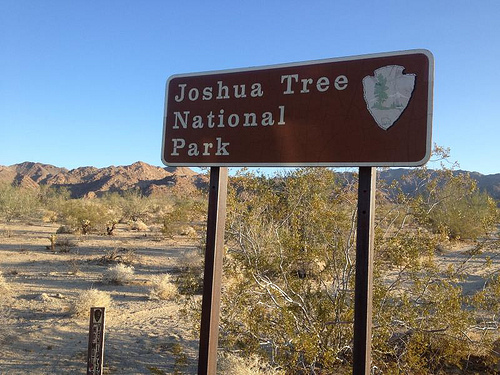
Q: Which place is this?
A: It is a park.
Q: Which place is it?
A: It is a park.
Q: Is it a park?
A: Yes, it is a park.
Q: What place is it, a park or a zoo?
A: It is a park.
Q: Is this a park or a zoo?
A: It is a park.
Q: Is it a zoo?
A: No, it is a park.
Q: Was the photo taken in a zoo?
A: No, the picture was taken in a park.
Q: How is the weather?
A: It is clear.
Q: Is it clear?
A: Yes, it is clear.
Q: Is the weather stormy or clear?
A: It is clear.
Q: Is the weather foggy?
A: No, it is clear.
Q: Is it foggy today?
A: No, it is clear.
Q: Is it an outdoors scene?
A: Yes, it is outdoors.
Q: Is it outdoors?
A: Yes, it is outdoors.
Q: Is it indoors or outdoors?
A: It is outdoors.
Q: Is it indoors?
A: No, it is outdoors.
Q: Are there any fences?
A: No, there are no fences.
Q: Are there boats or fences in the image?
A: No, there are no fences or boats.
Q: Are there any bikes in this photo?
A: No, there are no bikes.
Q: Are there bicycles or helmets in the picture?
A: No, there are no bicycles or helmets.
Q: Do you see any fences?
A: No, there are no fences.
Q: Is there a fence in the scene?
A: No, there are no fences.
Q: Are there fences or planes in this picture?
A: No, there are no fences or planes.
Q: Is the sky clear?
A: Yes, the sky is clear.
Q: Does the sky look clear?
A: Yes, the sky is clear.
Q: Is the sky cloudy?
A: No, the sky is clear.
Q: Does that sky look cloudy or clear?
A: The sky is clear.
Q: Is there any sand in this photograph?
A: Yes, there is sand.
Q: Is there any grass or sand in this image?
A: Yes, there is sand.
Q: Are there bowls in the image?
A: No, there are no bowls.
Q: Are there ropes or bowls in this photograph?
A: No, there are no bowls or ropes.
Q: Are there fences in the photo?
A: No, there are no fences.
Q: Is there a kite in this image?
A: No, there are no kites.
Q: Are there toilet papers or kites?
A: No, there are no kites or toilet papers.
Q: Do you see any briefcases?
A: No, there are no briefcases.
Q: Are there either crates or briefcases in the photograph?
A: No, there are no briefcases or crates.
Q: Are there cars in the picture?
A: No, there are no cars.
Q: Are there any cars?
A: No, there are no cars.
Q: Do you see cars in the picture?
A: No, there are no cars.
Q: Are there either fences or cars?
A: No, there are no cars or fences.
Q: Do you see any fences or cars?
A: No, there are no cars or fences.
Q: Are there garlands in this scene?
A: No, there are no garlands.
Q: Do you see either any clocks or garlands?
A: No, there are no garlands or clocks.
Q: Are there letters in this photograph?
A: Yes, there are letters.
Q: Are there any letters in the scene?
A: Yes, there are letters.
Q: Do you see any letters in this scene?
A: Yes, there are letters.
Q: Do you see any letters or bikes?
A: Yes, there are letters.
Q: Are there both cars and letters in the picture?
A: No, there are letters but no cars.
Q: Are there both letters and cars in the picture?
A: No, there are letters but no cars.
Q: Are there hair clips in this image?
A: No, there are no hair clips.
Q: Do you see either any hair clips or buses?
A: No, there are no hair clips or buses.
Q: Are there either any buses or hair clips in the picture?
A: No, there are no hair clips or buses.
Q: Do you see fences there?
A: No, there are no fences.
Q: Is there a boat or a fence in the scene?
A: No, there are no fences or boats.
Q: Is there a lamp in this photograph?
A: No, there are no lamps.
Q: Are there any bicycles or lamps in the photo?
A: No, there are no lamps or bicycles.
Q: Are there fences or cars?
A: No, there are no fences or cars.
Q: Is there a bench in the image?
A: No, there are no benches.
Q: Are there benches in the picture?
A: No, there are no benches.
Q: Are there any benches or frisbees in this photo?
A: No, there are no benches or frisbees.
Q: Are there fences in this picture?
A: No, there are no fences.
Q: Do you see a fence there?
A: No, there are no fences.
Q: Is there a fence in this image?
A: No, there are no fences.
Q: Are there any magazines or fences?
A: No, there are no fences or magazines.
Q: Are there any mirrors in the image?
A: No, there are no mirrors.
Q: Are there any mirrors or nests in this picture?
A: No, there are no mirrors or nests.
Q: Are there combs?
A: No, there are no combs.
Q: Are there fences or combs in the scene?
A: No, there are no combs or fences.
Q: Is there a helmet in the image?
A: No, there are no helmets.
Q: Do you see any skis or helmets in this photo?
A: No, there are no helmets or skis.